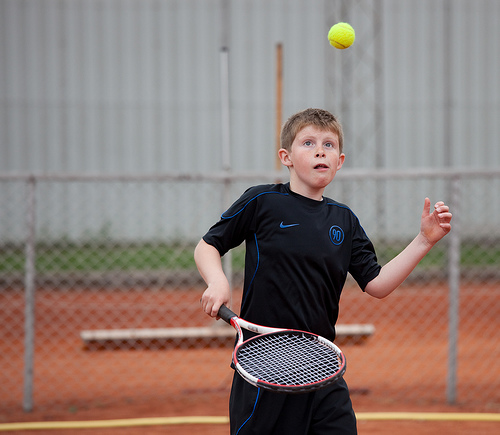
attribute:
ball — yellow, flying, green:
[328, 19, 356, 51]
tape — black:
[217, 305, 234, 322]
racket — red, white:
[218, 305, 346, 394]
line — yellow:
[1, 410, 497, 431]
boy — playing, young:
[193, 108, 451, 433]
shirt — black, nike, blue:
[200, 183, 380, 377]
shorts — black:
[230, 361, 358, 433]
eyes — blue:
[301, 140, 333, 150]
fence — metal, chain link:
[0, 164, 497, 411]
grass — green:
[0, 235, 497, 271]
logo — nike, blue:
[276, 218, 300, 232]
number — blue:
[326, 223, 348, 244]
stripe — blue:
[232, 386, 261, 433]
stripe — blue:
[242, 230, 263, 312]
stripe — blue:
[218, 187, 292, 223]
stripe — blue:
[318, 199, 348, 215]